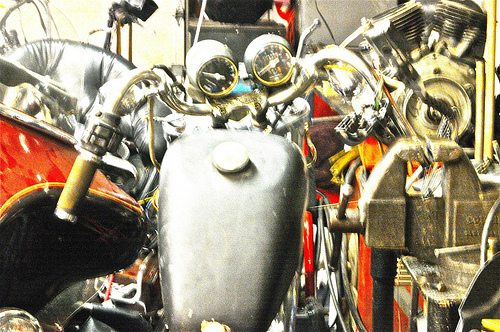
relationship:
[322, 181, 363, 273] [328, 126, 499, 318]
handle on vice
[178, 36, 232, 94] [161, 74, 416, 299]
gauge on motorcyle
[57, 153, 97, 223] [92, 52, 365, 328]
handle on motorcycle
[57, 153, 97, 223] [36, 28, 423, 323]
handle on motorcycle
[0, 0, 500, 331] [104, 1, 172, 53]
bike has parts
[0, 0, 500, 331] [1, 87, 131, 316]
bike has parts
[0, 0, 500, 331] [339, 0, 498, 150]
bike has engine parts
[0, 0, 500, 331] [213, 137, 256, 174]
bike has cap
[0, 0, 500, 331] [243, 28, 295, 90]
bike has speedometer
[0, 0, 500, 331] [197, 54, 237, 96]
bike has dials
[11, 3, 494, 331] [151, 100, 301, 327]
bike has fuel tank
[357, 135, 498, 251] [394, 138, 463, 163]
bench vise has teeth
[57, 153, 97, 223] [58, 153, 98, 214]
handle has handle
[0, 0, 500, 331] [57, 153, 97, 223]
bike has handle